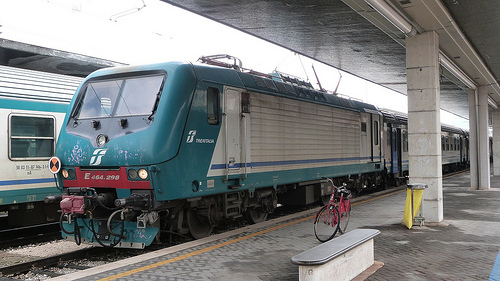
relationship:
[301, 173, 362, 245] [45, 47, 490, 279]
bicycle sitting near train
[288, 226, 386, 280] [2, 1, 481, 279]
bench at train station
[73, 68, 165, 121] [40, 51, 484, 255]
windshield of train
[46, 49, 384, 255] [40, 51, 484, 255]
car of train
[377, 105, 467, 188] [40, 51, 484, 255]
passenger car of train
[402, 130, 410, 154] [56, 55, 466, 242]
passenger window of train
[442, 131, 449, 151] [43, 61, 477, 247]
passenger window of train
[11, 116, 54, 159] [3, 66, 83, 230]
window on a train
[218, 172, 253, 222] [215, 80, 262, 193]
ladder below closed door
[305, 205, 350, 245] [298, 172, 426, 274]
wheel on bike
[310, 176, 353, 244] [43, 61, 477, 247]
bicycle near train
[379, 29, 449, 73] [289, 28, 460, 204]
lighting on train station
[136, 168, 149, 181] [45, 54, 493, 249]
head lights on train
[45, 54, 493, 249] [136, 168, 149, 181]
train with head lights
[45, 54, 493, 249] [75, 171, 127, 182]
train with paint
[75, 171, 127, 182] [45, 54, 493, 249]
paint on train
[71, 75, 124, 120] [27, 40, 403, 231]
windows on train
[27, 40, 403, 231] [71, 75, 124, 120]
train with windows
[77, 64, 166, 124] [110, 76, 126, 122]
window with bar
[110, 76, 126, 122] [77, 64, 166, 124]
bar on window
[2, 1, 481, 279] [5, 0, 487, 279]
train station in scene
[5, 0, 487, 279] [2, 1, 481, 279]
scene of train station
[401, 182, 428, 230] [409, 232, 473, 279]
bag on platform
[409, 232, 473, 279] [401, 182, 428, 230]
platform with bag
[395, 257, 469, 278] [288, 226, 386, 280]
cement under bench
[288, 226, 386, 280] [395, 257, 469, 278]
bench on cement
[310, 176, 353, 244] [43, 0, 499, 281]
bicycle on platform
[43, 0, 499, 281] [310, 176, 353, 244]
platform with bicycle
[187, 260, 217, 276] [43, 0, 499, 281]
cobblestone makes up platform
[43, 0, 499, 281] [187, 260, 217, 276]
platform made of cobblestone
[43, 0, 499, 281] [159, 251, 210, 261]
platform with line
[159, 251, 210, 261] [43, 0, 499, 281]
line on platform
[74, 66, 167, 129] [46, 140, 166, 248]
windows on engine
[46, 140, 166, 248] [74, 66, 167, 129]
engine with windows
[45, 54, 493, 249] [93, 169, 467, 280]
train next to line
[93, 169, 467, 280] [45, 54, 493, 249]
line beside train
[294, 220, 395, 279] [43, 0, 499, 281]
bench on platform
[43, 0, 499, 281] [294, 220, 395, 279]
platform under bench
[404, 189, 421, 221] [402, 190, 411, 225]
pole next to bag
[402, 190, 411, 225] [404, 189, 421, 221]
bag beside pole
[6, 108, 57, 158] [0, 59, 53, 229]
window on train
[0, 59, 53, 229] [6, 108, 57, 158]
train with window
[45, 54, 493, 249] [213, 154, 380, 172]
train with line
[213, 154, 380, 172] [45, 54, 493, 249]
line on train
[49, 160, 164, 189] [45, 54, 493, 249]
head lights on train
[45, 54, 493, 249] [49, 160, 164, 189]
train with head lights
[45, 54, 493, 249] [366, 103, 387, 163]
train with door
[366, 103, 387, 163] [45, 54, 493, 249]
door on train